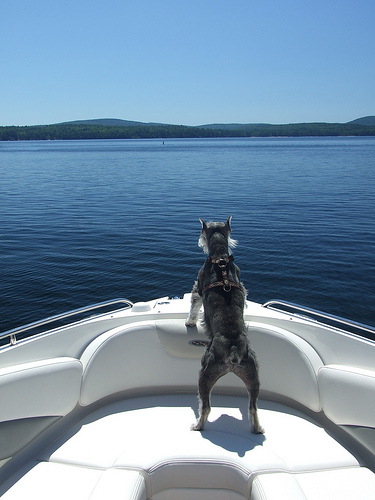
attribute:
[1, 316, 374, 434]
back seat cushions — white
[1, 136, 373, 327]
water — calm, blue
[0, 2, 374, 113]
sky — blue, clear blue